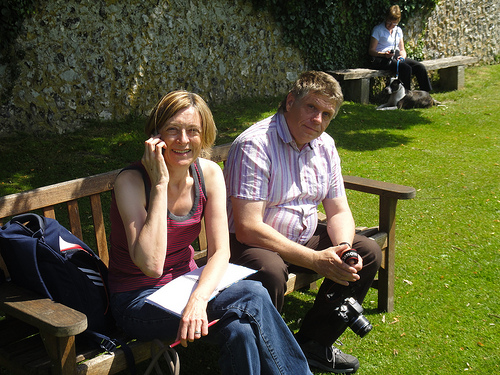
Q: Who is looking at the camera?
A: A man and a woman.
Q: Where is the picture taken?
A: A park.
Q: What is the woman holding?
A: A cell phone.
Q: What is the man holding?
A: A camera.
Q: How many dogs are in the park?
A: One.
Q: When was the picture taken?
A: Daytime.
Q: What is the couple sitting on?
A: A bench.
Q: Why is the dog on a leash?
A: So he won't run away.